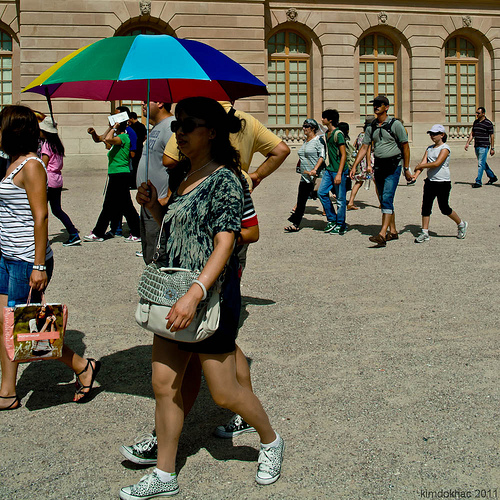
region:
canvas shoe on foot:
[253, 430, 285, 485]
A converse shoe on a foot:
[120, 427, 160, 464]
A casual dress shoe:
[69, 352, 98, 402]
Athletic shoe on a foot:
[412, 226, 427, 243]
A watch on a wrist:
[30, 262, 47, 272]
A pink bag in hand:
[2, 283, 68, 360]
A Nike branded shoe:
[80, 232, 102, 243]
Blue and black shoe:
[60, 231, 81, 246]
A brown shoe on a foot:
[367, 233, 385, 246]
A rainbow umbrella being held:
[18, 31, 269, 218]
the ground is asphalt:
[355, 398, 447, 466]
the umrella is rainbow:
[52, 13, 258, 95]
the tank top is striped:
[0, 186, 42, 251]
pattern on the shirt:
[165, 220, 224, 258]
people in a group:
[277, 81, 477, 222]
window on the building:
[423, 30, 488, 137]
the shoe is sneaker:
[260, 436, 305, 486]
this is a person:
[416, 117, 470, 254]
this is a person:
[354, 84, 440, 279]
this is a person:
[470, 93, 498, 181]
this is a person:
[291, 102, 335, 233]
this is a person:
[318, 105, 364, 235]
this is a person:
[112, 101, 283, 490]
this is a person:
[87, 92, 142, 250]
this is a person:
[458, 90, 495, 207]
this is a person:
[1, 105, 94, 421]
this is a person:
[21, 108, 108, 278]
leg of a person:
[118, 353, 219, 495]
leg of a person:
[205, 347, 284, 452]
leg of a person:
[3, 310, 35, 372]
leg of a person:
[46, 310, 106, 373]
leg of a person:
[283, 190, 323, 233]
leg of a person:
[329, 162, 362, 216]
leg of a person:
[358, 171, 403, 233]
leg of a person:
[405, 190, 445, 250]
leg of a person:
[437, 190, 483, 232]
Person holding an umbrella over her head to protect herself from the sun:
[8, 10, 349, 495]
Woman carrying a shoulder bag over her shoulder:
[91, 155, 290, 394]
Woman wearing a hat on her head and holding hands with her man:
[411, 121, 476, 266]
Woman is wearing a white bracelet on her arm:
[128, 255, 296, 378]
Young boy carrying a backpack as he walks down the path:
[314, 90, 380, 274]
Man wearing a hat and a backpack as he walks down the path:
[345, 66, 430, 279]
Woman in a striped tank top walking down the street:
[1, 100, 93, 402]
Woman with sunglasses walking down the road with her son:
[281, 95, 353, 267]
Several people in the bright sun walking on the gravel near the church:
[6, 20, 469, 488]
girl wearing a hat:
[404, 112, 469, 269]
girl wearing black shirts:
[411, 121, 471, 247]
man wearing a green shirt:
[354, 73, 409, 247]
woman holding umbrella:
[125, 90, 277, 496]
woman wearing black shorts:
[130, 87, 271, 495]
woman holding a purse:
[108, 97, 329, 495]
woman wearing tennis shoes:
[118, 97, 294, 497]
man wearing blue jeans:
[460, 105, 498, 192]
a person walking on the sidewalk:
[307, 106, 351, 203]